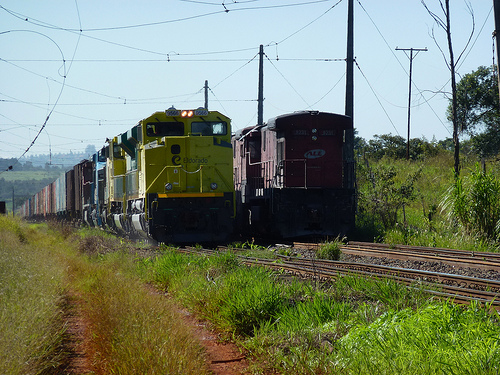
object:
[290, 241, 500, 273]
train tracks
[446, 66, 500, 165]
tree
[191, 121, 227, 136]
window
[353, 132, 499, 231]
bushes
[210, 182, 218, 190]
headlight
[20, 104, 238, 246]
train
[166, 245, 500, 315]
tracks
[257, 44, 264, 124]
power pole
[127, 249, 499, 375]
grass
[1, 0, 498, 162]
sky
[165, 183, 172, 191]
headlight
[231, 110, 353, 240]
train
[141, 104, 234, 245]
front